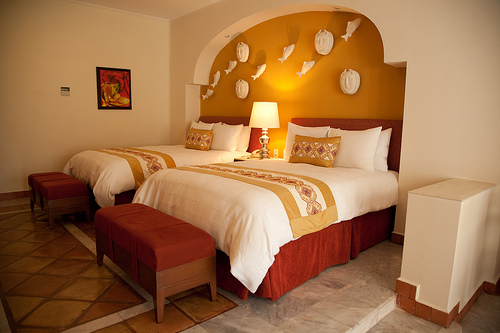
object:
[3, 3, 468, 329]
bedroom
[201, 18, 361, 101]
decoration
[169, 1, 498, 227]
wall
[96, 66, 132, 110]
painting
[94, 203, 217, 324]
ottoman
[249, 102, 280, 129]
shade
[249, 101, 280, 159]
lamp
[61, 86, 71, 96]
thermostat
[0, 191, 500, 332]
tiles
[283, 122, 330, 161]
pillow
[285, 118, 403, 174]
headboard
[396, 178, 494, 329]
pillar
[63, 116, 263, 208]
bed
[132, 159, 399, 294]
bedspread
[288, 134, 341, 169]
pillow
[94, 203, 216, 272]
cloth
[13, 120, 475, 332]
right of room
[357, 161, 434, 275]
to bed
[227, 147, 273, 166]
table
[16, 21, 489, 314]
indoor scene